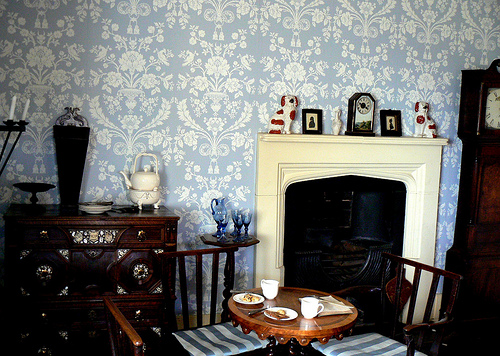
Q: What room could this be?
A: It is a kitchen.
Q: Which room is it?
A: It is a kitchen.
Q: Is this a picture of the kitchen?
A: Yes, it is showing the kitchen.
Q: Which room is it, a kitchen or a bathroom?
A: It is a kitchen.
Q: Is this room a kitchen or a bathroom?
A: It is a kitchen.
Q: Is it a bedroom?
A: No, it is a kitchen.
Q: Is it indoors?
A: Yes, it is indoors.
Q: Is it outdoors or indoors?
A: It is indoors.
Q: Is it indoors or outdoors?
A: It is indoors.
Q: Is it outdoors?
A: No, it is indoors.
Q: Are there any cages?
A: No, there are no cages.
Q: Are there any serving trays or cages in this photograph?
A: No, there are no cages or serving trays.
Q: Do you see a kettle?
A: Yes, there is a kettle.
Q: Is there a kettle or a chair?
A: Yes, there is a kettle.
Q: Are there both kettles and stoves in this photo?
A: No, there is a kettle but no stoves.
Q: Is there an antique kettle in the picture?
A: Yes, there is an antique kettle.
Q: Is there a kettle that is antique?
A: Yes, there is a kettle that is antique.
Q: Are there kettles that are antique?
A: Yes, there is a kettle that is antique.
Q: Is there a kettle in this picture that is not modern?
A: Yes, there is a antique kettle.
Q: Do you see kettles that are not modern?
A: Yes, there is a antique kettle.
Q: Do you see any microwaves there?
A: No, there are no microwaves.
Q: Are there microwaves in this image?
A: No, there are no microwaves.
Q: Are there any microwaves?
A: No, there are no microwaves.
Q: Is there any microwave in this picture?
A: No, there are no microwaves.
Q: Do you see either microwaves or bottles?
A: No, there are no microwaves or bottles.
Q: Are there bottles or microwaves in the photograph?
A: No, there are no microwaves or bottles.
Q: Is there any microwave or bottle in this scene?
A: No, there are no microwaves or bottles.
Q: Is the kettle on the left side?
A: Yes, the kettle is on the left of the image.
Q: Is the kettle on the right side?
A: No, the kettle is on the left of the image.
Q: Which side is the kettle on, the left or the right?
A: The kettle is on the left of the image.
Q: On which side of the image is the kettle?
A: The kettle is on the left of the image.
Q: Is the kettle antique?
A: Yes, the kettle is antique.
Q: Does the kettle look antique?
A: Yes, the kettle is antique.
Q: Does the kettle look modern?
A: No, the kettle is antique.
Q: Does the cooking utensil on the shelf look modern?
A: No, the kettle is antique.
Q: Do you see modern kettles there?
A: No, there is a kettle but it is antique.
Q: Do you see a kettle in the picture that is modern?
A: No, there is a kettle but it is antique.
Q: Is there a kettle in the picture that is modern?
A: No, there is a kettle but it is antique.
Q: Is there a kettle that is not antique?
A: No, there is a kettle but it is antique.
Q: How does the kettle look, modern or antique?
A: The kettle is antique.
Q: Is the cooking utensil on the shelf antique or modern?
A: The kettle is antique.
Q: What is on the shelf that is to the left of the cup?
A: The kettle is on the shelf.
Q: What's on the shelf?
A: The kettle is on the shelf.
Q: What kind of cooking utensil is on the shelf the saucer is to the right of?
A: The cooking utensil is a kettle.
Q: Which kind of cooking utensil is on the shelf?
A: The cooking utensil is a kettle.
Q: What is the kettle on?
A: The kettle is on the shelf.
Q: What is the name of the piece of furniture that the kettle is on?
A: The piece of furniture is a shelf.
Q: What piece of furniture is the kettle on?
A: The kettle is on the shelf.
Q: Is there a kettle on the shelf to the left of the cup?
A: Yes, there is a kettle on the shelf.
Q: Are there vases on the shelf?
A: No, there is a kettle on the shelf.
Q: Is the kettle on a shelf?
A: Yes, the kettle is on a shelf.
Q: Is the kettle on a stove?
A: No, the kettle is on a shelf.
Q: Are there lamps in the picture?
A: No, there are no lamps.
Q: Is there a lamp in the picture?
A: No, there are no lamps.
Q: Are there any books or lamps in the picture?
A: No, there are no lamps or books.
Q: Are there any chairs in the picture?
A: Yes, there is a chair.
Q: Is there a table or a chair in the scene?
A: Yes, there is a chair.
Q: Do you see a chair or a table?
A: Yes, there is a chair.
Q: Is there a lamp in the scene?
A: No, there are no lamps.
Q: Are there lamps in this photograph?
A: No, there are no lamps.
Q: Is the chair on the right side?
A: Yes, the chair is on the right of the image.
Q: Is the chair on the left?
A: No, the chair is on the right of the image.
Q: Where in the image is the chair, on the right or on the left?
A: The chair is on the right of the image.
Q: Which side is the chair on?
A: The chair is on the right of the image.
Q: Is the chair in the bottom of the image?
A: Yes, the chair is in the bottom of the image.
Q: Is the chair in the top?
A: No, the chair is in the bottom of the image.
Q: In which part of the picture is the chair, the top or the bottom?
A: The chair is in the bottom of the image.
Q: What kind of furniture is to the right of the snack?
A: The piece of furniture is a chair.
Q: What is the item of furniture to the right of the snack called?
A: The piece of furniture is a chair.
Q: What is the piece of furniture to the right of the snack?
A: The piece of furniture is a chair.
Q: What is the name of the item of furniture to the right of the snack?
A: The piece of furniture is a chair.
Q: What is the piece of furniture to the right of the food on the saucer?
A: The piece of furniture is a chair.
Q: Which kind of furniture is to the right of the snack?
A: The piece of furniture is a chair.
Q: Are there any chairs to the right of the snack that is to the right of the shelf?
A: Yes, there is a chair to the right of the snack.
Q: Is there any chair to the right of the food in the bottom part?
A: Yes, there is a chair to the right of the snack.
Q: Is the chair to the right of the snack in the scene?
A: Yes, the chair is to the right of the snack.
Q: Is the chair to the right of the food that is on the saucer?
A: Yes, the chair is to the right of the snack.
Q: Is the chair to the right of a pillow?
A: No, the chair is to the right of the snack.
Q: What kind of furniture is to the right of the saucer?
A: The piece of furniture is a chair.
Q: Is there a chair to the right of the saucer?
A: Yes, there is a chair to the right of the saucer.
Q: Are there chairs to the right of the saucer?
A: Yes, there is a chair to the right of the saucer.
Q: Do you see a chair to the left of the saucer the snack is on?
A: No, the chair is to the right of the saucer.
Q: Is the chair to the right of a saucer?
A: Yes, the chair is to the right of a saucer.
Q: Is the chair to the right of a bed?
A: No, the chair is to the right of a saucer.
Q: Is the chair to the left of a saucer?
A: No, the chair is to the right of a saucer.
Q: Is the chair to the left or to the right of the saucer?
A: The chair is to the right of the saucer.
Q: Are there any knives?
A: No, there are no knives.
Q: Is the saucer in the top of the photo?
A: No, the saucer is in the bottom of the image.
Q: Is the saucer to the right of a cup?
A: No, the saucer is to the left of a cup.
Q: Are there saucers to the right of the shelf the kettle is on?
A: Yes, there is a saucer to the right of the shelf.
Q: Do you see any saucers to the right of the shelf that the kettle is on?
A: Yes, there is a saucer to the right of the shelf.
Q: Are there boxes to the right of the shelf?
A: No, there is a saucer to the right of the shelf.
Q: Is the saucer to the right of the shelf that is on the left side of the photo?
A: Yes, the saucer is to the right of the shelf.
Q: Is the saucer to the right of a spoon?
A: No, the saucer is to the right of the shelf.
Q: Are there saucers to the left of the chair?
A: Yes, there is a saucer to the left of the chair.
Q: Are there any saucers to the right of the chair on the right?
A: No, the saucer is to the left of the chair.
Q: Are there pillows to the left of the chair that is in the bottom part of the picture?
A: No, there is a saucer to the left of the chair.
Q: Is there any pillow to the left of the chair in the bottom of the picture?
A: No, there is a saucer to the left of the chair.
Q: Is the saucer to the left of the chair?
A: Yes, the saucer is to the left of the chair.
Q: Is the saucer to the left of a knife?
A: No, the saucer is to the left of the chair.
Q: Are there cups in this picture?
A: Yes, there is a cup.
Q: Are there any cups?
A: Yes, there is a cup.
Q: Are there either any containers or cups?
A: Yes, there is a cup.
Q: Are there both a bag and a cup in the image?
A: No, there is a cup but no bags.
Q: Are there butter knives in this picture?
A: No, there are no butter knives.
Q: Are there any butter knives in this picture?
A: No, there are no butter knives.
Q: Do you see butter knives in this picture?
A: No, there are no butter knives.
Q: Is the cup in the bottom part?
A: Yes, the cup is in the bottom of the image.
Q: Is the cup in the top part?
A: No, the cup is in the bottom of the image.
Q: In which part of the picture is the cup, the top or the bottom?
A: The cup is in the bottom of the image.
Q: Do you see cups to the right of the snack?
A: Yes, there is a cup to the right of the snack.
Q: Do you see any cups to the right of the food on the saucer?
A: Yes, there is a cup to the right of the snack.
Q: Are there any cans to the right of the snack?
A: No, there is a cup to the right of the snack.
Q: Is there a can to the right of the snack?
A: No, there is a cup to the right of the snack.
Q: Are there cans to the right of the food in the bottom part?
A: No, there is a cup to the right of the snack.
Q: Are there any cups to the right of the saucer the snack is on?
A: Yes, there is a cup to the right of the saucer.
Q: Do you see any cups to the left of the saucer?
A: No, the cup is to the right of the saucer.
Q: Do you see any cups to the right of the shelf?
A: Yes, there is a cup to the right of the shelf.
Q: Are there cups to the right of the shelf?
A: Yes, there is a cup to the right of the shelf.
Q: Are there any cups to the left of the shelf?
A: No, the cup is to the right of the shelf.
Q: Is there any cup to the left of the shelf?
A: No, the cup is to the right of the shelf.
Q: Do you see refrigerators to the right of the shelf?
A: No, there is a cup to the right of the shelf.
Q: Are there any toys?
A: No, there are no toys.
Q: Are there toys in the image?
A: No, there are no toys.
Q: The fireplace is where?
A: The fireplace is in the kitchen.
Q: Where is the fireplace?
A: The fireplace is in the kitchen.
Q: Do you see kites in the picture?
A: No, there are no kites.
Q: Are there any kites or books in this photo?
A: No, there are no kites or books.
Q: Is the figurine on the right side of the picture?
A: Yes, the figurine is on the right of the image.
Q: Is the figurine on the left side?
A: No, the figurine is on the right of the image.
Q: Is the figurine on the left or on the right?
A: The figurine is on the right of the image.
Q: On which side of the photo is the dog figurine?
A: The figurine is on the right of the image.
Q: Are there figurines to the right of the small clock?
A: Yes, there is a figurine to the right of the clock.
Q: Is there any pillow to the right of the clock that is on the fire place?
A: No, there is a figurine to the right of the clock.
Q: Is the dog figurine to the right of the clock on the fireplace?
A: Yes, the figurine is to the right of the clock.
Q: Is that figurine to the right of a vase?
A: No, the figurine is to the right of the clock.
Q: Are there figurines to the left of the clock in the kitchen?
A: Yes, there is a figurine to the left of the clock.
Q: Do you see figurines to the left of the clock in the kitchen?
A: Yes, there is a figurine to the left of the clock.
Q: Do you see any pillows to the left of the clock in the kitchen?
A: No, there is a figurine to the left of the clock.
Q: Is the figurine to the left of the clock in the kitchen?
A: Yes, the figurine is to the left of the clock.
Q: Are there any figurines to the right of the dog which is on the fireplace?
A: Yes, there is a figurine to the right of the dog.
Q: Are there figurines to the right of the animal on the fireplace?
A: Yes, there is a figurine to the right of the dog.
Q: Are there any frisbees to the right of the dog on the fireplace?
A: No, there is a figurine to the right of the dog.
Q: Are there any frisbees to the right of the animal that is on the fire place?
A: No, there is a figurine to the right of the dog.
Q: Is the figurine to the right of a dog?
A: Yes, the figurine is to the right of a dog.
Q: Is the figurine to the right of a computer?
A: No, the figurine is to the right of a dog.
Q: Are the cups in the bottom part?
A: Yes, the cups are in the bottom of the image.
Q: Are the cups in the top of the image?
A: No, the cups are in the bottom of the image.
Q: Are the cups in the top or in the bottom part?
A: The cups are in the bottom of the image.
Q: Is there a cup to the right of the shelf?
A: Yes, there are cups to the right of the shelf.